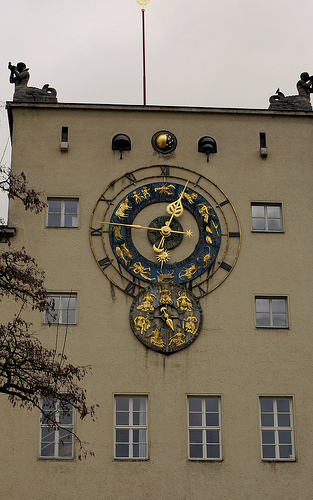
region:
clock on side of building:
[90, 161, 238, 307]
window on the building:
[181, 388, 223, 465]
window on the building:
[256, 393, 304, 468]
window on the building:
[110, 387, 151, 465]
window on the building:
[29, 389, 91, 465]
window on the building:
[42, 287, 80, 337]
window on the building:
[244, 290, 305, 342]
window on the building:
[244, 195, 284, 244]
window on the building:
[40, 194, 81, 232]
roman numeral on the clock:
[156, 166, 169, 186]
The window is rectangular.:
[35, 386, 83, 466]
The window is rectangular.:
[103, 383, 160, 469]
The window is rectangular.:
[177, 383, 230, 466]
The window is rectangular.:
[251, 381, 302, 474]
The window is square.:
[38, 274, 97, 330]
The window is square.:
[35, 186, 86, 242]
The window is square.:
[243, 184, 293, 246]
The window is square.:
[244, 287, 298, 337]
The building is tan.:
[0, 52, 311, 498]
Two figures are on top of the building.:
[2, 44, 311, 498]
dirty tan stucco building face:
[0, 459, 312, 499]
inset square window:
[257, 394, 296, 460]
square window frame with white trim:
[259, 429, 278, 445]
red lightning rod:
[136, 0, 150, 105]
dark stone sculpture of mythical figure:
[6, 58, 59, 101]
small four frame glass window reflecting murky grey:
[250, 200, 284, 233]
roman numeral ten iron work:
[96, 191, 113, 207]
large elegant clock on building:
[88, 160, 244, 300]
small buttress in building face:
[257, 131, 269, 159]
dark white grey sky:
[159, 6, 311, 63]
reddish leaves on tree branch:
[11, 330, 60, 371]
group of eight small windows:
[184, 388, 235, 482]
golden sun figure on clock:
[153, 248, 171, 267]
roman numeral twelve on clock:
[155, 162, 178, 183]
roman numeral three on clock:
[217, 221, 248, 245]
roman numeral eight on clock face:
[95, 251, 118, 275]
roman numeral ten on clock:
[98, 184, 116, 217]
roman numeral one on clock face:
[195, 170, 219, 193]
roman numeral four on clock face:
[220, 257, 241, 278]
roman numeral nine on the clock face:
[87, 221, 107, 242]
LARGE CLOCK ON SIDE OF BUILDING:
[59, 158, 277, 355]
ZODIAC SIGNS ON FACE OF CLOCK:
[119, 182, 217, 286]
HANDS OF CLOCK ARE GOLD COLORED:
[114, 187, 215, 281]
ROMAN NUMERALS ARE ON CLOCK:
[72, 163, 254, 301]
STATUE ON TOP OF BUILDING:
[1, 52, 65, 114]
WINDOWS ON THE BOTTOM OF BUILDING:
[13, 375, 304, 474]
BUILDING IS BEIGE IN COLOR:
[16, 288, 306, 425]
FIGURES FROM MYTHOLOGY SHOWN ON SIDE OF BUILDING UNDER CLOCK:
[106, 276, 225, 372]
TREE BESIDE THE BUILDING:
[3, 222, 99, 425]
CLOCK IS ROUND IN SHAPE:
[77, 159, 263, 305]